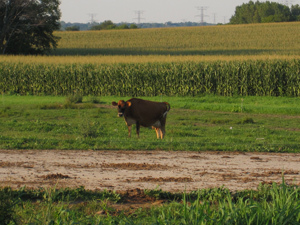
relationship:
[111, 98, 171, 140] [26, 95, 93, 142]
cow in grass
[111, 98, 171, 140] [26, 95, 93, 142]
cow on grass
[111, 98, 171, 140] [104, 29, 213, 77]
cow near field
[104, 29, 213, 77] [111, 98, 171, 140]
field near cow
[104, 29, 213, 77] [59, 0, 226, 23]
field below sky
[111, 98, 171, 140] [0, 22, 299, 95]
cow standing in corn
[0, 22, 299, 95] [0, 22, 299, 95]
corn growing in corn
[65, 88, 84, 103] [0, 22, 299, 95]
shrub growing in corn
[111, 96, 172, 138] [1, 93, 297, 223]
cow standing in grass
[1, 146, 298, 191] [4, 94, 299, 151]
path beside grass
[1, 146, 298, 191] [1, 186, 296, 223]
path beside grass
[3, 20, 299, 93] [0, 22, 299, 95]
corn in corn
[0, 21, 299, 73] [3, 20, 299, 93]
tassels on corn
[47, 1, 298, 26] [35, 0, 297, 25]
cloud in sky